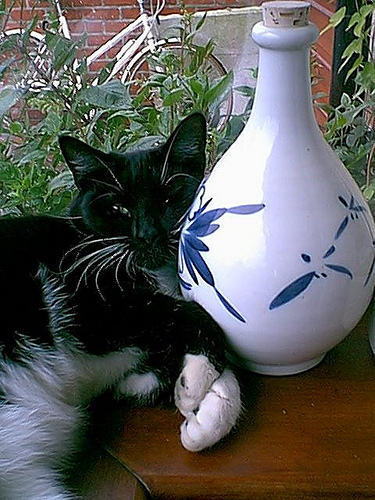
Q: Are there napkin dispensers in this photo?
A: No, there are no napkin dispensers.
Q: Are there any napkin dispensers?
A: No, there are no napkin dispensers.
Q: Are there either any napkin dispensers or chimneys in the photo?
A: No, there are no napkin dispensers or chimneys.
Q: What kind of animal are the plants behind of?
A: The plants are behind the cat.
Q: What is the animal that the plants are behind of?
A: The animal is a cat.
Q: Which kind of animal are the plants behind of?
A: The plants are behind the cat.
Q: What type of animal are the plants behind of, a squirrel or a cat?
A: The plants are behind a cat.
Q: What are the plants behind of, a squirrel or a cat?
A: The plants are behind a cat.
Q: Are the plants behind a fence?
A: No, the plants are behind a cat.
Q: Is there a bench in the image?
A: No, there are no benches.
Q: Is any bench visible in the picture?
A: No, there are no benches.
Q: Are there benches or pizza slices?
A: No, there are no benches or pizza slices.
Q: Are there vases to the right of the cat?
A: Yes, there is a vase to the right of the cat.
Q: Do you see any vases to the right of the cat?
A: Yes, there is a vase to the right of the cat.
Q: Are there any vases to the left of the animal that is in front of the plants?
A: No, the vase is to the right of the cat.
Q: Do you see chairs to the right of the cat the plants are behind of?
A: No, there is a vase to the right of the cat.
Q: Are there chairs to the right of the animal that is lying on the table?
A: No, there is a vase to the right of the cat.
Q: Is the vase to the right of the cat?
A: Yes, the vase is to the right of the cat.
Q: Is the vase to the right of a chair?
A: No, the vase is to the right of the cat.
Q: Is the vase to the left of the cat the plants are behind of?
A: No, the vase is to the right of the cat.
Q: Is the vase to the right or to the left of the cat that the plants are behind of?
A: The vase is to the right of the cat.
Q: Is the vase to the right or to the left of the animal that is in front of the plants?
A: The vase is to the right of the cat.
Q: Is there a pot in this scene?
A: No, there are no pots.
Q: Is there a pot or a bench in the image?
A: No, there are no pots or benches.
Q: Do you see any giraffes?
A: No, there are no giraffes.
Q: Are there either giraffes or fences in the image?
A: No, there are no giraffes or fences.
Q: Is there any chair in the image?
A: No, there are no chairs.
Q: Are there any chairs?
A: No, there are no chairs.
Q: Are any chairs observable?
A: No, there are no chairs.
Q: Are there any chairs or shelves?
A: No, there are no chairs or shelves.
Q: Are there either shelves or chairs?
A: No, there are no chairs or shelves.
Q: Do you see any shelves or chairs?
A: No, there are no chairs or shelves.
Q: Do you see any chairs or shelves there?
A: No, there are no chairs or shelves.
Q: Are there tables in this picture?
A: Yes, there is a table.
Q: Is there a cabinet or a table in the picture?
A: Yes, there is a table.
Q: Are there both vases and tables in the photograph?
A: Yes, there are both a table and a vase.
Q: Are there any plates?
A: No, there are no plates.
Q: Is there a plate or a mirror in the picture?
A: No, there are no plates or mirrors.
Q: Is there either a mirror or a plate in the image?
A: No, there are no plates or mirrors.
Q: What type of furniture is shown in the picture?
A: The furniture is a table.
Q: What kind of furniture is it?
A: The piece of furniture is a table.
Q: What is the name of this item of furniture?
A: This is a table.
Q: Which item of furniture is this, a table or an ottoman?
A: This is a table.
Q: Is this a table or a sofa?
A: This is a table.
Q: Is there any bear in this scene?
A: No, there are no bears.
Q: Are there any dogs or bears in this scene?
A: No, there are no bears or dogs.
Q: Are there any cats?
A: Yes, there is a cat.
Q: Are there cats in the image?
A: Yes, there is a cat.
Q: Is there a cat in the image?
A: Yes, there is a cat.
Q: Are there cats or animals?
A: Yes, there is a cat.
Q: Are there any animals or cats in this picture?
A: Yes, there is a cat.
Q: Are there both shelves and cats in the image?
A: No, there is a cat but no shelves.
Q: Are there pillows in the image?
A: No, there are no pillows.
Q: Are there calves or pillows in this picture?
A: No, there are no pillows or calves.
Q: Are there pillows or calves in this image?
A: No, there are no pillows or calves.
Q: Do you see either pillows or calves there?
A: No, there are no pillows or calves.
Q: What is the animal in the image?
A: The animal is a cat.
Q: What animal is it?
A: The animal is a cat.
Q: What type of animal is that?
A: This is a cat.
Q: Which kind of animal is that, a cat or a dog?
A: This is a cat.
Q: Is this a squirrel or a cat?
A: This is a cat.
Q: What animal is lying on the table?
A: The cat is lying on the table.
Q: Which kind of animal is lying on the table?
A: The animal is a cat.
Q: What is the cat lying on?
A: The cat is lying on the table.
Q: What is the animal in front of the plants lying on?
A: The cat is lying on the table.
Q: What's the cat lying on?
A: The cat is lying on the table.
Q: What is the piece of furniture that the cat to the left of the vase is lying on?
A: The piece of furniture is a table.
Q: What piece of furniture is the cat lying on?
A: The cat is lying on the table.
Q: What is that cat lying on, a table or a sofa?
A: The cat is lying on a table.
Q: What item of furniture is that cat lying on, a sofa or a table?
A: The cat is lying on a table.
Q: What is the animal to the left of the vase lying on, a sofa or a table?
A: The cat is lying on a table.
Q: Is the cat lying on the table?
A: Yes, the cat is lying on the table.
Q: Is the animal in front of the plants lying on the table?
A: Yes, the cat is lying on the table.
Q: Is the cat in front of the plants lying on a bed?
A: No, the cat is lying on the table.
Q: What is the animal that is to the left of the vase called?
A: The animal is a cat.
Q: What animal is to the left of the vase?
A: The animal is a cat.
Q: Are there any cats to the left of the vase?
A: Yes, there is a cat to the left of the vase.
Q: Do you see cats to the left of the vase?
A: Yes, there is a cat to the left of the vase.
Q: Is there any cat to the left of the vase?
A: Yes, there is a cat to the left of the vase.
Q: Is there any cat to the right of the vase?
A: No, the cat is to the left of the vase.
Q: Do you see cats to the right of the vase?
A: No, the cat is to the left of the vase.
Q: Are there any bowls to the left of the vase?
A: No, there is a cat to the left of the vase.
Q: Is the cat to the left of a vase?
A: Yes, the cat is to the left of a vase.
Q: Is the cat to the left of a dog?
A: No, the cat is to the left of a vase.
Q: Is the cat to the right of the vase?
A: No, the cat is to the left of the vase.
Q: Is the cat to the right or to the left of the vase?
A: The cat is to the left of the vase.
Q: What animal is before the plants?
A: The cat is in front of the plants.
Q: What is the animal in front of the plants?
A: The animal is a cat.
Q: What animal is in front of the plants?
A: The animal is a cat.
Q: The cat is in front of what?
A: The cat is in front of the plants.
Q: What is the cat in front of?
A: The cat is in front of the plants.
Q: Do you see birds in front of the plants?
A: No, there is a cat in front of the plants.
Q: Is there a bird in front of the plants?
A: No, there is a cat in front of the plants.